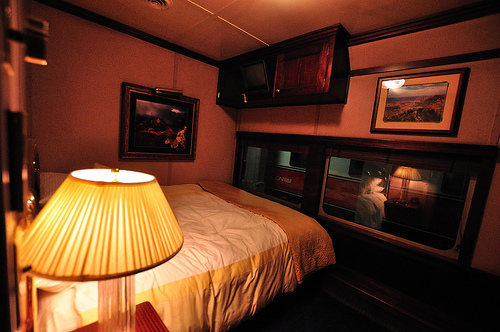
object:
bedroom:
[0, 2, 498, 328]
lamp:
[21, 167, 188, 331]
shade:
[22, 167, 181, 281]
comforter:
[14, 182, 334, 332]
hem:
[79, 257, 301, 330]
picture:
[118, 80, 200, 159]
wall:
[22, 2, 236, 178]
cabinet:
[214, 24, 349, 105]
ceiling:
[55, 0, 498, 120]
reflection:
[356, 164, 459, 224]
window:
[314, 148, 470, 255]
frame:
[120, 79, 201, 160]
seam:
[163, 44, 178, 188]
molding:
[50, 3, 223, 69]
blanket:
[232, 230, 341, 284]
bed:
[15, 172, 335, 330]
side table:
[70, 301, 166, 332]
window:
[241, 133, 310, 203]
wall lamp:
[378, 79, 407, 92]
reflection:
[377, 76, 409, 92]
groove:
[83, 186, 130, 268]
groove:
[60, 186, 130, 270]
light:
[66, 161, 160, 187]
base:
[95, 278, 142, 332]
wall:
[230, 1, 498, 182]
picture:
[372, 72, 463, 133]